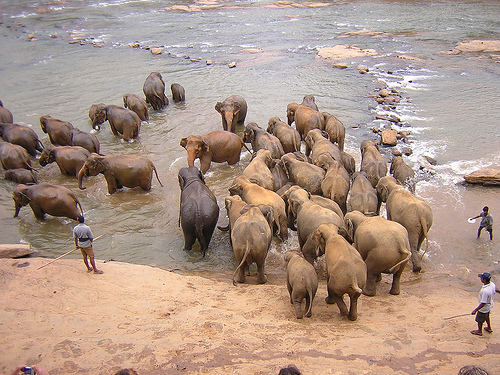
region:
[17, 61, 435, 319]
group of elephants in water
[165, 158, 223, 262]
darkest brown elephant in water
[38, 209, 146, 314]
person with grey shirt and stick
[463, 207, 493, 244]
small child in water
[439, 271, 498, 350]
person in white shirt and blue hat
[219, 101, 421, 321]
herd of dry elephants to right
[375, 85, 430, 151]
rocks in the water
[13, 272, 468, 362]
bank next to the water and elephants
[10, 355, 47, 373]
person's hands holding a phone to left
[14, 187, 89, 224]
THIS IS AN ELEPHANT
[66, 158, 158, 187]
THIS IS AN ELEPHANT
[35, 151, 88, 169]
THIS IS AN ELEPHANT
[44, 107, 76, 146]
THIS IS AN ELEPHANT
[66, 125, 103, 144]
THIS IS AN ELEPHANT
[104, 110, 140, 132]
THIS IS AN ELEPHANT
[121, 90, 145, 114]
THIS IS AN ELEPHANT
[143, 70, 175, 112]
THIS IS AN ELEPHANT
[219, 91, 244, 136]
THIS IS AN ELEPHANT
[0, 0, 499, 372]
A large group of elephants standing in water.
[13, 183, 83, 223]
An elephant with its trunk in the water.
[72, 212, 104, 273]
A man standing by the edge of the water.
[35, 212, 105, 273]
The man is holding a long wooden stick.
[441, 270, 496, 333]
A man behind the elephants with a stick in his hand.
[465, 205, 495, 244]
A boy in the water holding a white object.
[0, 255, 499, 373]
A dirt ground with wet areas.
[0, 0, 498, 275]
A large body of flowing water.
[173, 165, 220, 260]
An overhead angle of a glistening wet elephant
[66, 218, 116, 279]
A man standing on the edge of a muddy bank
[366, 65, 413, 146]
A collection of rocks forming a line in the surf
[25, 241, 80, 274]
A long pale stick being held in a man's hand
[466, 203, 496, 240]
A child standing in shallow water, holding a Frisbee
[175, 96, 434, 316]
A throng of elephants in or near the water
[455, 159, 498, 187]
A jagged light brown stone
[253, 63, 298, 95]
Greenish-gray rippling water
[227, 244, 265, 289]
A swinging elephant tail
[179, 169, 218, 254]
the elephant is gray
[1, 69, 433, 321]
a group of elephants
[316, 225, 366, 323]
the elephant is brown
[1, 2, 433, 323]
elephants going in the water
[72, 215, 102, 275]
a man is standing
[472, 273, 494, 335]
man looking at elephants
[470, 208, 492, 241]
kid in the water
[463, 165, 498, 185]
the rock is brown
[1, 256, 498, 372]
sand on the shore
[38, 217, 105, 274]
man holding a stick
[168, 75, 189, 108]
one small elephant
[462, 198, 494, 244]
the man is in the river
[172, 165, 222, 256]
one black elephant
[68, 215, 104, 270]
the man is holding a stick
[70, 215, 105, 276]
the man is standing up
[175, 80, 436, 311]
one large group of elephants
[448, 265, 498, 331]
the man is wearing a white shirt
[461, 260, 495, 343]
the man have a blue cap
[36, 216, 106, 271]
the man is holding a stick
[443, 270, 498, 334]
the man is holding a stick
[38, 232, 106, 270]
the stick is long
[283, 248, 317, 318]
the elephant is gray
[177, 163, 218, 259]
the elephant is dark gray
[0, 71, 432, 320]
the elephants in a group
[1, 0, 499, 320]
the elephants in the water and going into the water